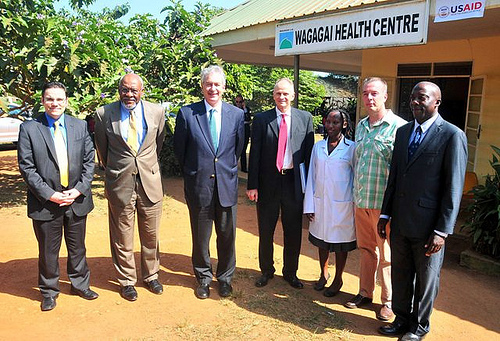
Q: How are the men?
A: Standing.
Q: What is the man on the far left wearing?
A: Glasses.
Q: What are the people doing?
A: Posing for a photo.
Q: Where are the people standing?
A: In front of Wagagai Health Centre.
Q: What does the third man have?
A: A pink tie.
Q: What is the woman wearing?
A: A labcoat.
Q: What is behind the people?
A: Trees.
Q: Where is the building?
A: Behind the people.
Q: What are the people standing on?
A: Dirt.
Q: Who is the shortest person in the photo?
A: The woman in white.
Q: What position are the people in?
A: Standing.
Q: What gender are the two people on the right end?
A: Male.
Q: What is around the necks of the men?
A: Ties.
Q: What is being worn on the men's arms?
A: Jackets.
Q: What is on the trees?
A: Green leaves.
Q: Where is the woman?
A: Third person from the right.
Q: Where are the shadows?
A: On the ground.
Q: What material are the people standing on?
A: Dirt.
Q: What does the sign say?
A: Wagagai Health Center.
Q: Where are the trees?
A: Behind the people.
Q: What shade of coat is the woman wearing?
A: White.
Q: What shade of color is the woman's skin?
A: Dark brown.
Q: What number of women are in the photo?
A: 1.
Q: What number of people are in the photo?
A: 7.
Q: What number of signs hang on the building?
A: 2.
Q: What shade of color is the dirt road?
A: Brown.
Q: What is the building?
A: Wagaga Health Centre.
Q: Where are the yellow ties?
A: First two men from the left.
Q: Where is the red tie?
A: Man in the center.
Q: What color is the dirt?
A: Brown.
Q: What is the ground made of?
A: Dirt.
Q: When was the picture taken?
A: Daytime.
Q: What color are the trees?
A: Green.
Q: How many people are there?
A: Seven.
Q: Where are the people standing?
A: On the dirt.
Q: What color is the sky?
A: Blue.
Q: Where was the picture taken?
A: In front of building.